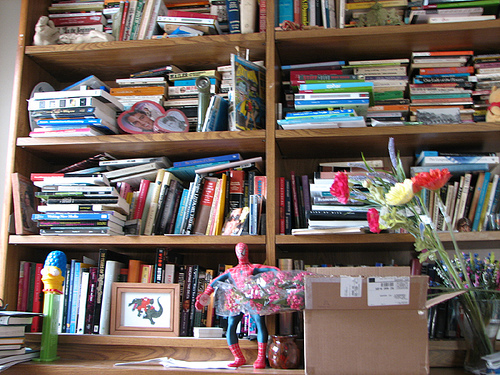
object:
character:
[40, 249, 68, 360]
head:
[40, 251, 65, 290]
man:
[193, 241, 285, 369]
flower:
[329, 172, 351, 204]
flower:
[380, 178, 416, 206]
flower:
[411, 166, 448, 191]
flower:
[364, 207, 381, 232]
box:
[299, 262, 428, 370]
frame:
[152, 106, 191, 134]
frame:
[117, 97, 165, 132]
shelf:
[275, 124, 497, 137]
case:
[278, 3, 496, 372]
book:
[134, 180, 150, 228]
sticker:
[368, 277, 411, 309]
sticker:
[339, 273, 364, 297]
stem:
[404, 204, 487, 347]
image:
[162, 116, 185, 128]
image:
[128, 107, 153, 129]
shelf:
[13, 350, 304, 372]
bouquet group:
[325, 131, 496, 354]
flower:
[383, 136, 397, 176]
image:
[127, 297, 163, 328]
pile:
[0, 311, 37, 370]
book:
[227, 53, 261, 129]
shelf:
[17, 131, 268, 147]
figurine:
[483, 88, 497, 121]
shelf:
[6, 141, 269, 246]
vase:
[451, 295, 498, 372]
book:
[171, 155, 241, 169]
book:
[31, 211, 120, 224]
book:
[193, 176, 211, 237]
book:
[249, 193, 257, 233]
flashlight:
[194, 75, 210, 133]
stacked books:
[279, 42, 496, 128]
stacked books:
[21, 43, 265, 136]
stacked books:
[12, 145, 266, 234]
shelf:
[27, 33, 266, 56]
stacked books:
[31, 4, 265, 40]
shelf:
[277, 233, 498, 247]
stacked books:
[275, 139, 495, 239]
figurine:
[350, 4, 405, 28]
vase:
[266, 331, 298, 369]